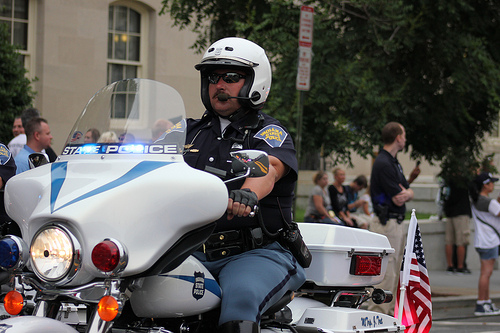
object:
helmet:
[194, 36, 271, 107]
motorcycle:
[4, 76, 407, 331]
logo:
[59, 145, 180, 155]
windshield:
[59, 78, 188, 154]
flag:
[395, 205, 433, 332]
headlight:
[27, 221, 82, 285]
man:
[370, 120, 414, 329]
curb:
[365, 264, 500, 318]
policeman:
[141, 38, 311, 332]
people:
[308, 168, 376, 230]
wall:
[400, 218, 499, 267]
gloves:
[227, 187, 259, 212]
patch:
[253, 123, 287, 148]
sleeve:
[248, 115, 299, 181]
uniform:
[149, 119, 309, 330]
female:
[470, 172, 500, 314]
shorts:
[473, 243, 499, 257]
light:
[111, 29, 128, 42]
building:
[1, 1, 215, 167]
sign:
[58, 142, 179, 155]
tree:
[158, 1, 499, 167]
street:
[395, 313, 498, 332]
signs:
[297, 4, 312, 94]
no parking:
[300, 48, 311, 64]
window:
[104, 2, 143, 121]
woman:
[469, 171, 499, 316]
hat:
[477, 171, 497, 182]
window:
[1, 0, 29, 72]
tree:
[1, 25, 43, 145]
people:
[11, 116, 134, 176]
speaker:
[218, 92, 262, 103]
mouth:
[210, 92, 232, 103]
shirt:
[148, 110, 297, 235]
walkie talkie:
[272, 198, 314, 268]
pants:
[192, 249, 307, 320]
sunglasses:
[205, 70, 252, 83]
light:
[89, 238, 121, 273]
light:
[0, 236, 20, 268]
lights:
[1, 291, 119, 320]